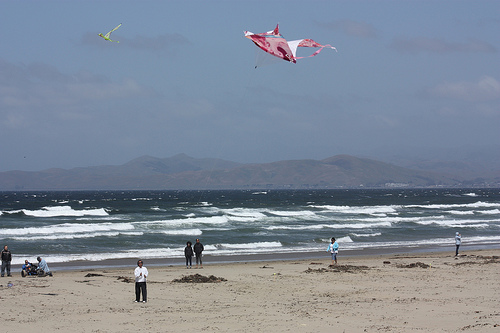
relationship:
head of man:
[135, 257, 143, 265] [132, 253, 148, 302]